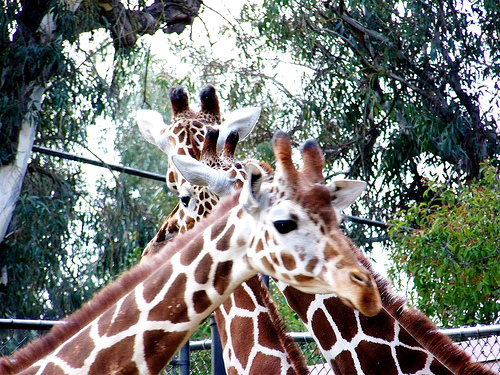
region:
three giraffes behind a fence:
[27, 75, 477, 370]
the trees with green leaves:
[348, 25, 487, 186]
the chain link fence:
[3, 308, 496, 367]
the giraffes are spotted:
[4, 68, 484, 373]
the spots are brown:
[8, 82, 494, 362]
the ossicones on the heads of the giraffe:
[163, 75, 328, 175]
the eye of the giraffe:
[251, 204, 322, 256]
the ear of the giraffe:
[123, 105, 176, 161]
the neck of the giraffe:
[25, 205, 247, 372]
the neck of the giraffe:
[296, 312, 499, 371]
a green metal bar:
[14, 124, 434, 264]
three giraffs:
[108, 67, 382, 320]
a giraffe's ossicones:
[167, 85, 228, 117]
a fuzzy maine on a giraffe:
[2, 181, 240, 374]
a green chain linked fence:
[447, 315, 499, 351]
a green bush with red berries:
[382, 173, 498, 335]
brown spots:
[92, 287, 178, 337]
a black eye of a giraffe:
[267, 212, 310, 243]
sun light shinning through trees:
[65, 89, 128, 189]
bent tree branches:
[336, 14, 467, 123]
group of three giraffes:
[2, 90, 494, 373]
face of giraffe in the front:
[223, 131, 382, 312]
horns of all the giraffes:
[168, 82, 330, 179]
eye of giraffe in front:
[269, 208, 306, 238]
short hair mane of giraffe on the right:
[345, 236, 477, 371]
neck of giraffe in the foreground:
[2, 211, 252, 373]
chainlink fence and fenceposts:
[0, 300, 499, 369]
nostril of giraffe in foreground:
[343, 266, 375, 291]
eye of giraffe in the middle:
[176, 188, 201, 215]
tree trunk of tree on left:
[2, 0, 47, 247]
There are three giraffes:
[20, 67, 448, 354]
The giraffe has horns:
[225, 127, 366, 202]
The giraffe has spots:
[20, 131, 387, 368]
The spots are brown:
[56, 135, 366, 370]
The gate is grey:
[10, 290, 485, 365]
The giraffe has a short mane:
[13, 133, 285, 361]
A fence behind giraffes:
[0, 290, 480, 360]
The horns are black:
[155, 70, 226, 135]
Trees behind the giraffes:
[16, 15, 481, 330]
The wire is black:
[27, 123, 446, 233]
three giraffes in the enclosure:
[28, 81, 485, 373]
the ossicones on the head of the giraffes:
[154, 80, 327, 184]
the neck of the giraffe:
[212, 295, 302, 373]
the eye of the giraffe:
[265, 211, 309, 241]